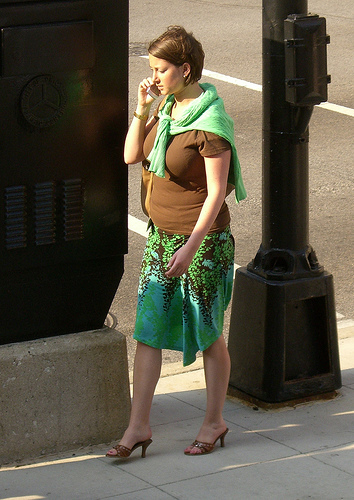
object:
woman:
[103, 25, 236, 463]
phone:
[147, 74, 162, 99]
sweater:
[146, 81, 248, 202]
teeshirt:
[141, 95, 231, 232]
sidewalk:
[0, 330, 353, 498]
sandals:
[106, 435, 152, 458]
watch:
[132, 110, 149, 122]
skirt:
[133, 224, 235, 367]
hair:
[147, 26, 207, 87]